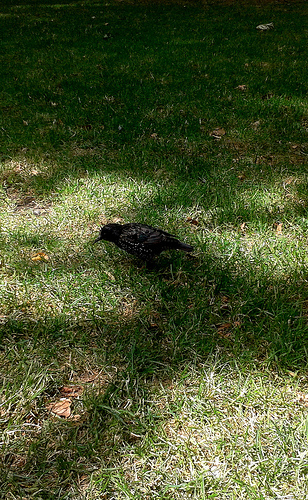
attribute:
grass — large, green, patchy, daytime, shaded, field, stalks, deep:
[3, 2, 306, 487]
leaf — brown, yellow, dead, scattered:
[42, 378, 84, 429]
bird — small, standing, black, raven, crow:
[90, 216, 192, 286]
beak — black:
[91, 236, 108, 246]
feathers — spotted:
[126, 223, 156, 255]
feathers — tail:
[172, 235, 195, 258]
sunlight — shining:
[14, 155, 307, 343]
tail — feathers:
[175, 236, 197, 268]